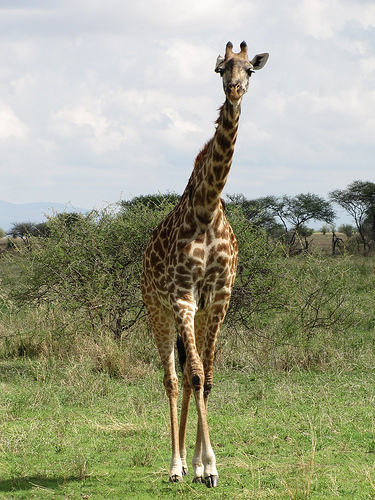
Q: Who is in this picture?
A: No one.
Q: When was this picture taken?
A: Daytime.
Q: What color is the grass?
A: Green.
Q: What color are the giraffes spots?
A: Brown.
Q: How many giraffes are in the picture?
A: One.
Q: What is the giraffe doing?
A: Walking.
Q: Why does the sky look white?
A: Cloudy.